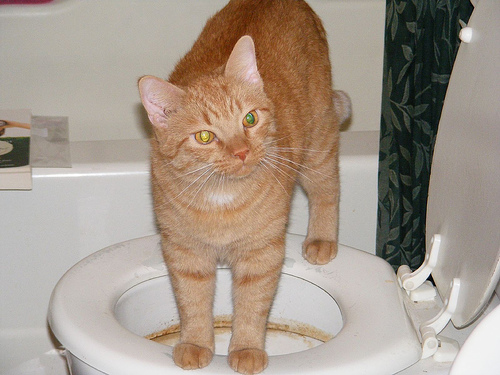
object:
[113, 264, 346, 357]
ring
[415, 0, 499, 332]
lid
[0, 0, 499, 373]
toilet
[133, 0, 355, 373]
cat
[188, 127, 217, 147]
eye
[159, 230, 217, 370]
legs